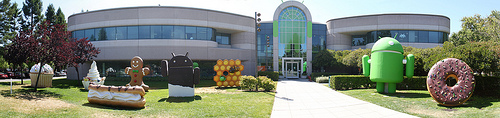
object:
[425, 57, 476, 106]
donut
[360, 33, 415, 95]
android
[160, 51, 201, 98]
statue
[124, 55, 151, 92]
gingerbread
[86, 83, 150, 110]
cupcake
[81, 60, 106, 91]
ice cream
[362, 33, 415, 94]
robot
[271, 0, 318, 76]
section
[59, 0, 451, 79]
building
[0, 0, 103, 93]
tree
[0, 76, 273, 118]
grass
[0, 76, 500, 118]
field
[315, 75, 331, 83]
boulder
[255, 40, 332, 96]
front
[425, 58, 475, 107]
doughnut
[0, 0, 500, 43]
sky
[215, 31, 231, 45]
window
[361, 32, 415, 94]
sculpture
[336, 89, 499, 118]
lawn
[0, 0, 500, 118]
picture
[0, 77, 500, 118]
ground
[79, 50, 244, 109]
dessert